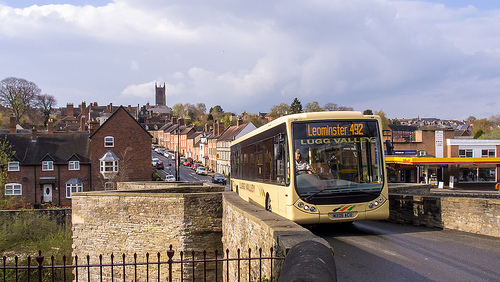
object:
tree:
[1, 76, 41, 129]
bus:
[228, 111, 393, 229]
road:
[152, 147, 500, 281]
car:
[196, 167, 211, 176]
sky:
[0, 1, 499, 122]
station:
[389, 155, 497, 190]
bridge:
[68, 179, 500, 281]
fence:
[1, 244, 292, 281]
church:
[144, 81, 177, 125]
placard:
[304, 120, 366, 140]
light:
[298, 201, 316, 212]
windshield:
[293, 138, 384, 197]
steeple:
[154, 81, 166, 107]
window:
[68, 161, 80, 171]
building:
[0, 103, 153, 211]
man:
[286, 147, 313, 176]